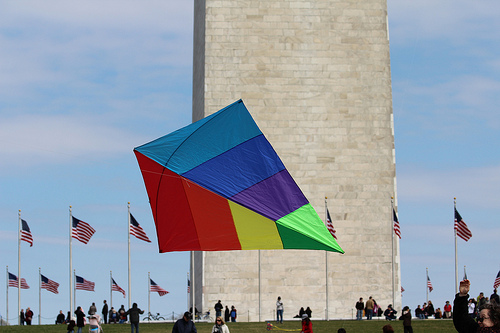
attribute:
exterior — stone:
[206, 2, 391, 320]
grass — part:
[320, 319, 352, 327]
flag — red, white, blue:
[445, 190, 482, 265]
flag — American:
[453, 202, 473, 243]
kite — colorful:
[127, 94, 352, 260]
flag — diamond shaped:
[116, 81, 357, 268]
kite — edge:
[240, 116, 246, 130]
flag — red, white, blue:
[64, 210, 102, 246]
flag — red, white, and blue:
[446, 195, 471, 250]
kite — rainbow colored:
[67, 97, 402, 287]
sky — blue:
[398, 46, 474, 119]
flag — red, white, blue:
[57, 202, 101, 247]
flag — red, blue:
[126, 202, 151, 316]